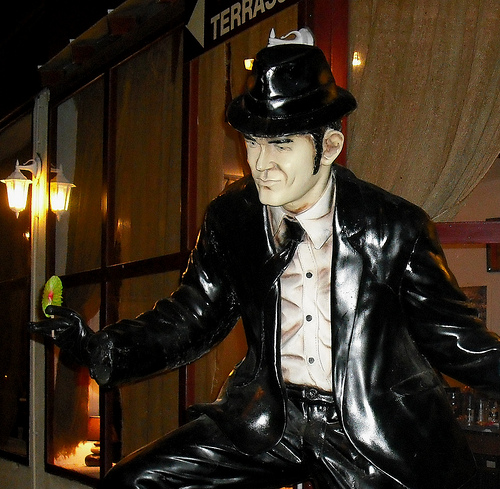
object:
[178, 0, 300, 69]
sign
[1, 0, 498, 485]
building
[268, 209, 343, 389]
shirt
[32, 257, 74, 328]
green grass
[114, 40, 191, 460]
curtain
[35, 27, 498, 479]
statue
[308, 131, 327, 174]
hair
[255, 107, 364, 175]
hair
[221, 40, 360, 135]
hat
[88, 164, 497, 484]
coat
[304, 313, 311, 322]
button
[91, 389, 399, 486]
black pants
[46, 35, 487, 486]
man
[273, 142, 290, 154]
eye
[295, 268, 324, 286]
button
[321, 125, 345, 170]
ear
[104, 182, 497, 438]
jacket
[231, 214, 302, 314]
tie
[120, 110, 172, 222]
window